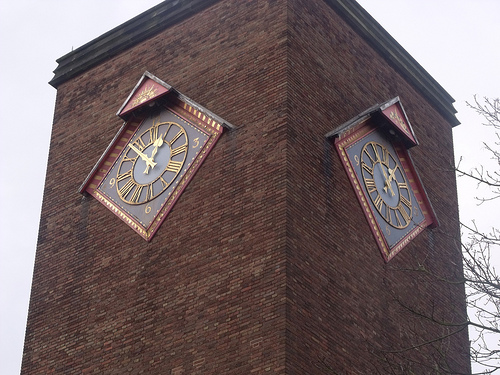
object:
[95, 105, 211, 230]
clock face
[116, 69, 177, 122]
ornament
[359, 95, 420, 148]
ornament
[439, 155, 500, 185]
branches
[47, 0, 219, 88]
border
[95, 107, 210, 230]
clock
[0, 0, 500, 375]
blue sky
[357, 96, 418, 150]
triangle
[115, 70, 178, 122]
triangle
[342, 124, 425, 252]
clock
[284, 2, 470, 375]
brown wall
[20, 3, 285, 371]
brown wall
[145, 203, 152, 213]
number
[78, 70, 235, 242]
edge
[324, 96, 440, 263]
edge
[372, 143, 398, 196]
gold hands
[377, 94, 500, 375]
bare tree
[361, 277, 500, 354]
branches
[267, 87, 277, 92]
bricks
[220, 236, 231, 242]
bricks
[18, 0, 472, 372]
brick tower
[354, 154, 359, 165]
numbers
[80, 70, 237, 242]
ornate design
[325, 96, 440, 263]
ornate design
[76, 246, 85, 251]
brick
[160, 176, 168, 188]
roman numerals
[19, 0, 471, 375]
structure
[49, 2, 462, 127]
roof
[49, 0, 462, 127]
railing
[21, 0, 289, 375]
side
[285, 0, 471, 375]
side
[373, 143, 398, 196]
12:49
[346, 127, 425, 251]
time